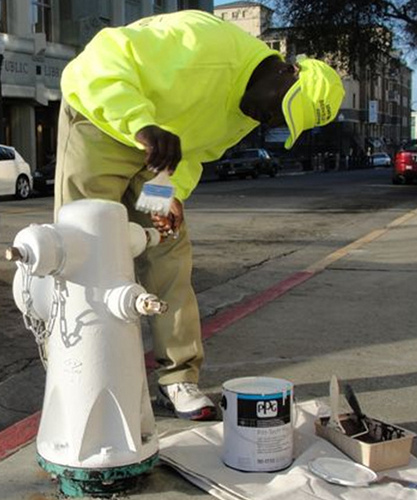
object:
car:
[0, 145, 34, 200]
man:
[53, 8, 345, 422]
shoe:
[153, 382, 217, 421]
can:
[222, 376, 294, 472]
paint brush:
[135, 171, 176, 217]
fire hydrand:
[5, 197, 173, 500]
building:
[0, 0, 416, 176]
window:
[35, 0, 52, 43]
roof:
[213, 2, 275, 13]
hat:
[282, 54, 346, 151]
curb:
[205, 289, 269, 338]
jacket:
[60, 9, 283, 208]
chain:
[14, 243, 61, 343]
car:
[390, 148, 417, 185]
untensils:
[326, 372, 370, 438]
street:
[0, 167, 417, 499]